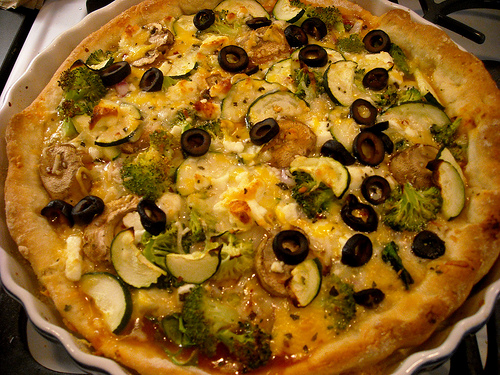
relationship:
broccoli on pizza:
[115, 130, 180, 199] [4, 2, 496, 371]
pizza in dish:
[4, 2, 496, 371] [18, 20, 68, 80]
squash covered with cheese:
[173, 155, 253, 206] [206, 165, 260, 206]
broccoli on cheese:
[380, 178, 444, 233] [38, 12, 476, 373]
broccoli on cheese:
[172, 281, 259, 353] [38, 12, 476, 373]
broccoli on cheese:
[115, 132, 180, 199] [38, 12, 476, 373]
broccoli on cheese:
[52, 63, 110, 120] [38, 12, 476, 373]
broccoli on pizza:
[380, 181, 444, 233] [4, 2, 496, 371]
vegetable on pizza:
[180, 289, 240, 358] [4, 2, 496, 371]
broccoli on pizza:
[52, 63, 110, 120] [4, 2, 496, 371]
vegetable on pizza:
[325, 273, 355, 333] [4, 2, 496, 371]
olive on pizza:
[334, 229, 379, 271] [4, 2, 496, 371]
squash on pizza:
[258, 245, 350, 308] [0, 0, 500, 375]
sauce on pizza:
[131, 308, 300, 373] [4, 2, 496, 371]